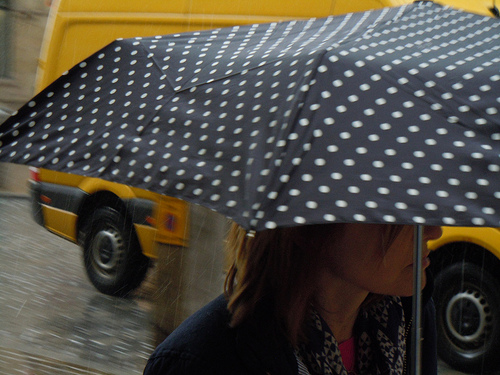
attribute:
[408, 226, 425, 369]
post — chrome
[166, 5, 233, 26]
car — yellow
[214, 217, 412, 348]
hair — medium length, brown, straight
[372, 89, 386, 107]
dot — white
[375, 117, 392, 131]
dot — white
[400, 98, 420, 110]
dot — white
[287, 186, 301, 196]
dot — white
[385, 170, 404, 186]
dot — white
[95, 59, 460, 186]
polka dots — Black , white 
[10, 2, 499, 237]
umbrella — black, unfurled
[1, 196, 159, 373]
street — asphalt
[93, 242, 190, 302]
rain — heavy 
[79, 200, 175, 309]
tire — black, rubber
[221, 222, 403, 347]
hair — dark , brown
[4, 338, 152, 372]
sidewalk — bricked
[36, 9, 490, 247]
van — yellow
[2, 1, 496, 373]
umbrella — black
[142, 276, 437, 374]
jacket — blue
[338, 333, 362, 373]
shirt — pink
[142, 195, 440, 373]
tarmac — Black 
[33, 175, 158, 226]
trim — gray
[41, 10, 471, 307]
van — large, yellow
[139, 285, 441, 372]
shirt — pink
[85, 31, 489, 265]
umbrella — black, white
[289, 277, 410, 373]
scarf — black, white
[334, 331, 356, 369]
shirt — pink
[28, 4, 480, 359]
van — yellow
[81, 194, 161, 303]
wheel — silver